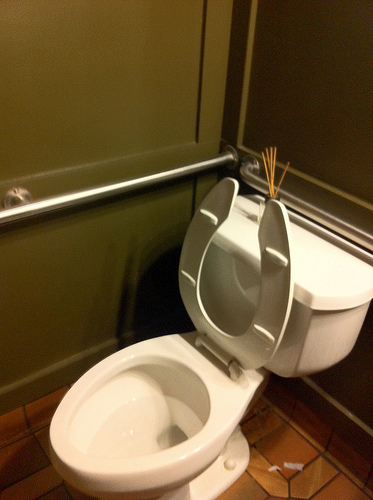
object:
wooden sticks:
[272, 161, 291, 202]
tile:
[289, 452, 338, 496]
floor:
[0, 386, 372, 500]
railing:
[0, 144, 237, 229]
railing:
[237, 158, 373, 255]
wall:
[0, 0, 233, 411]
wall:
[217, 0, 372, 460]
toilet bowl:
[40, 332, 261, 499]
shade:
[109, 223, 193, 346]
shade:
[129, 360, 210, 426]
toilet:
[46, 178, 373, 499]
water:
[90, 390, 198, 460]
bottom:
[144, 428, 251, 500]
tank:
[199, 195, 372, 383]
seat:
[175, 176, 295, 374]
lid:
[177, 176, 295, 371]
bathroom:
[0, 0, 371, 498]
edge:
[264, 198, 296, 369]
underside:
[177, 177, 290, 372]